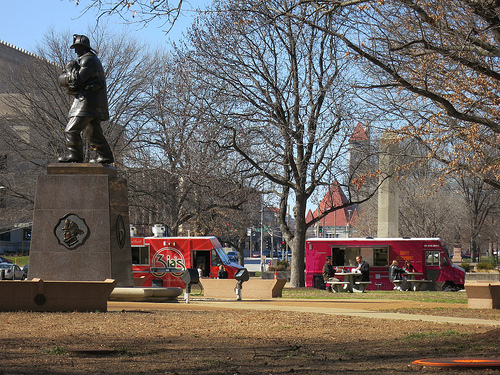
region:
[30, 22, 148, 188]
statue in the background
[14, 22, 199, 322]
a black statue in the background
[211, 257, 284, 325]
lights on the ground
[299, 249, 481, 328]
tables in the background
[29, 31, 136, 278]
a statue of a firefighter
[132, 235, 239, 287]
a food truck parked in the street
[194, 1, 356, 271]
a large leafless tree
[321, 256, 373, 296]
people sitting at a table eating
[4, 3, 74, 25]
a clear blue sky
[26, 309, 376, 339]
an area of dry grass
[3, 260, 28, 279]
a car parked on the street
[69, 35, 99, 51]
the helmet of a firefighter statue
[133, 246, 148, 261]
the window of a food truck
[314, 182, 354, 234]
the roof of a building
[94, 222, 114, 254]
edge of a monument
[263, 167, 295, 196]
part of a branch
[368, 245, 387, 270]
part of a window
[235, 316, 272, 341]
part of a fround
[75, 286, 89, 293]
part of an edge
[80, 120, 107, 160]
part of a statue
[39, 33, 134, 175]
statue of fireman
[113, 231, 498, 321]
two red food trucks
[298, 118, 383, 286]
building with red roof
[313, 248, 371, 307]
two men sitting at a table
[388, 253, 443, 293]
two women sitting at a table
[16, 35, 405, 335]
trees without leaves on them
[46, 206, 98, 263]
place of firemen head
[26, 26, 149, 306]
statue of fireman is large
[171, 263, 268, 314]
lights to shin on statue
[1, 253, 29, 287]
car parked on road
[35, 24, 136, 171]
a statue of a fireman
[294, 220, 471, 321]
the truck is red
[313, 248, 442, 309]
people sitting at tables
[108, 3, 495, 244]
the trees are bare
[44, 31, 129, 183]
the statue is gray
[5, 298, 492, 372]
the grass is brown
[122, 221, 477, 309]
both trucks are red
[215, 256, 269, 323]
a light pointing at the statue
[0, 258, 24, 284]
a white car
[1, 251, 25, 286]
the car is parked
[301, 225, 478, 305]
a purple vending truck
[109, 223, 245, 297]
a red vending truck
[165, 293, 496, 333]
a concrete sidewalk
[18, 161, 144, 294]
the concrete base of a statue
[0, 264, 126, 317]
a concrete bench next to a statue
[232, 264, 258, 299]
a light directed at a statue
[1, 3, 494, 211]
a pale blue sky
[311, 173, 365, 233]
the pointed roof of a building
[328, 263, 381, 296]
a table next to a ending truck